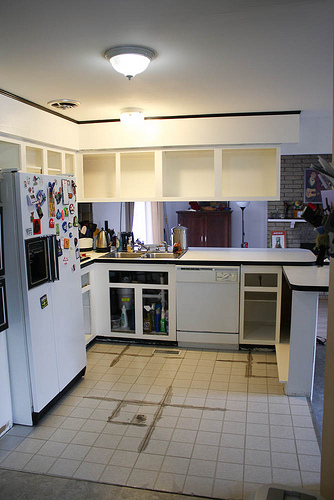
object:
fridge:
[1, 167, 87, 425]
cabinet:
[96, 262, 176, 346]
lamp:
[105, 47, 153, 82]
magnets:
[30, 186, 79, 238]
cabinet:
[81, 153, 275, 200]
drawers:
[106, 270, 170, 284]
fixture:
[101, 44, 158, 81]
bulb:
[110, 53, 149, 76]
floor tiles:
[4, 343, 309, 496]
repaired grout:
[96, 339, 184, 363]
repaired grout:
[219, 349, 279, 380]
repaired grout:
[85, 383, 224, 448]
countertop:
[79, 237, 320, 269]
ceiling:
[39, 10, 322, 129]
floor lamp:
[235, 201, 250, 245]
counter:
[179, 240, 320, 260]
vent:
[151, 345, 184, 356]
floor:
[4, 337, 326, 493]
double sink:
[102, 249, 177, 265]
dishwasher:
[171, 261, 241, 354]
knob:
[221, 270, 232, 282]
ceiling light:
[109, 35, 155, 84]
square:
[163, 143, 229, 192]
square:
[80, 150, 188, 189]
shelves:
[7, 138, 295, 200]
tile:
[142, 358, 165, 371]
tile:
[188, 377, 211, 389]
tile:
[168, 426, 199, 444]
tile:
[88, 407, 117, 420]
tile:
[97, 370, 122, 381]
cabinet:
[175, 208, 232, 248]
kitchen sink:
[105, 249, 183, 267]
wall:
[272, 150, 328, 252]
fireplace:
[295, 238, 331, 282]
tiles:
[203, 433, 276, 467]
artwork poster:
[271, 230, 287, 249]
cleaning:
[115, 283, 168, 328]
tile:
[121, 366, 143, 376]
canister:
[170, 223, 189, 250]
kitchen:
[1, 42, 326, 498]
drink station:
[26, 236, 60, 289]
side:
[92, 258, 314, 266]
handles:
[133, 284, 142, 297]